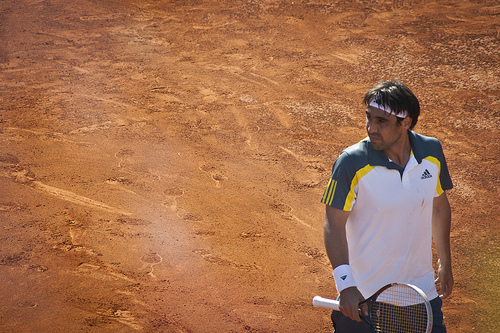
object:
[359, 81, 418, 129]
hair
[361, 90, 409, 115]
head band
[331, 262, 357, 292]
band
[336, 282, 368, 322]
hand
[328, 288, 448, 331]
shorts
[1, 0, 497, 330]
court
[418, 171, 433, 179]
insignia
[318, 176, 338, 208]
stripes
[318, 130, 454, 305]
blue shirt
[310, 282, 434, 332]
racket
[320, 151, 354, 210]
sleeve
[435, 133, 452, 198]
sleeve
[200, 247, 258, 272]
foot prints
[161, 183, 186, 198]
dirt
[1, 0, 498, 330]
ground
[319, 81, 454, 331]
man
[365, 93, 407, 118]
headband